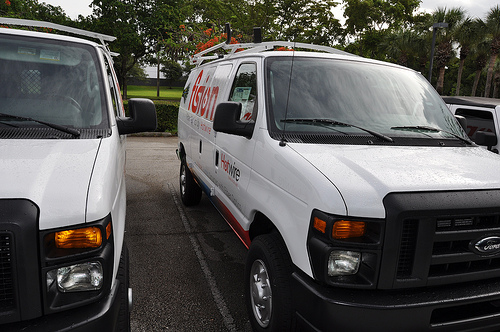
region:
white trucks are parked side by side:
[5, 16, 497, 326]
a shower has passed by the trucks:
[10, 20, 498, 316]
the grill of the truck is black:
[382, 187, 499, 289]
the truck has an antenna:
[270, 8, 307, 159]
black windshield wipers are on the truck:
[272, 107, 477, 144]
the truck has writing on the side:
[179, 57, 266, 243]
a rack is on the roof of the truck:
[188, 23, 374, 66]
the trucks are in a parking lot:
[1, 1, 496, 324]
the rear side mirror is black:
[114, 92, 159, 138]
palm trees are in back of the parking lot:
[398, 2, 499, 99]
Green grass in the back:
[131, 83, 187, 100]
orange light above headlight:
[306, 204, 377, 246]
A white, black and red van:
[178, 50, 472, 272]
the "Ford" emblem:
[465, 231, 499, 256]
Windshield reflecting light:
[277, 65, 449, 135]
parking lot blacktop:
[136, 157, 177, 327]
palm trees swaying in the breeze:
[416, 19, 489, 90]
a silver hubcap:
[238, 263, 283, 320]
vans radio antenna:
[286, 10, 289, 153]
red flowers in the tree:
[164, 20, 293, 68]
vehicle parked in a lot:
[164, 19, 496, 329]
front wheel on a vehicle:
[229, 220, 310, 330]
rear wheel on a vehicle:
[172, 140, 211, 215]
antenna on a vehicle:
[275, 6, 304, 160]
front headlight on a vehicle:
[322, 241, 372, 292]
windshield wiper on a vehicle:
[274, 107, 397, 155]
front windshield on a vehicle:
[257, 48, 481, 152]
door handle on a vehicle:
[208, 146, 223, 175]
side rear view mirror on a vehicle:
[208, 94, 263, 149]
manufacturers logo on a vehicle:
[468, 228, 498, 259]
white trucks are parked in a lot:
[0, 16, 499, 319]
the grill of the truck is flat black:
[379, 186, 499, 288]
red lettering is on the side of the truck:
[172, 38, 308, 263]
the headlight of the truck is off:
[314, 243, 376, 285]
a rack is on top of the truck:
[184, 34, 361, 66]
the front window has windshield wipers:
[284, 104, 467, 144]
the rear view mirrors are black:
[208, 99, 257, 143]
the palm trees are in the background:
[425, 3, 499, 99]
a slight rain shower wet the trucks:
[51, 135, 498, 247]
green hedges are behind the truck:
[100, 97, 185, 144]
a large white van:
[171, 41, 495, 329]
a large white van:
[0, 13, 133, 324]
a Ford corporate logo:
[469, 235, 496, 253]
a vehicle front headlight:
[325, 248, 361, 281]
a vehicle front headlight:
[47, 258, 104, 298]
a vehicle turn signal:
[49, 226, 107, 246]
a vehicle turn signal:
[328, 215, 365, 241]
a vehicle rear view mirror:
[205, 98, 252, 140]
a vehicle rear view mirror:
[109, 89, 161, 137]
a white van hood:
[284, 130, 498, 210]